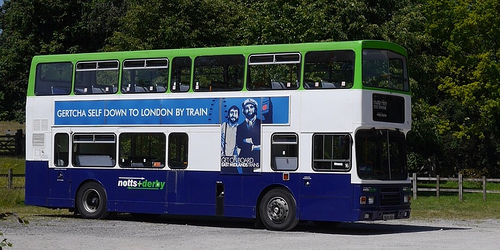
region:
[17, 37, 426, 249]
A double decker bus that is blue white and green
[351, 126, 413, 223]
The windshield on the bus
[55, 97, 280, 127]
An advertisement on the bus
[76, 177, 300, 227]
The wheels on the bus go round and round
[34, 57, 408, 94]
The upper deck of the bus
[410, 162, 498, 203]
A fence made from hedge posts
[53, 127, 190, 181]
Windows for the passengers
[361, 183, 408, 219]
Headlights on the front of the bus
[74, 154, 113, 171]
A seat inside the bus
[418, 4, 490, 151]
The trees are full and green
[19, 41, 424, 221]
blue, white, and green bus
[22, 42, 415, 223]
double decket bus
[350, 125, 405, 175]
front windshield of bus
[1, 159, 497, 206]
wood fenceline behind bus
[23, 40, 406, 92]
green top of bus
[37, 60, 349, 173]
windows on side of bus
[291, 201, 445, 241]
shadow of bus on road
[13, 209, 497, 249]
road bus is on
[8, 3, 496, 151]
trees behind the fenceline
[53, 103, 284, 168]
advertisement printed on side of bus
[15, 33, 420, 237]
a double-decker bus driving down a wooded road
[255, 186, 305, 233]
a front wheel of a double-decker bus driving down the road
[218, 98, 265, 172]
a picture of two men on the side of a double-decker bus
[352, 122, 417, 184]
the front window of a double-decker bus driving down a road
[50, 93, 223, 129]
words on a sign on a double-decker bus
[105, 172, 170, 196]
words on a sign on a double-decker bus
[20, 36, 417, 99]
the top part of a double-decker bus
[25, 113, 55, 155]
vents on the back side of a double-decker bus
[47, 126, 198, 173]
windows on the side of a double-decker bus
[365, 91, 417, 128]
the middle front window on a double-decker bus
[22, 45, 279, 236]
This is a bus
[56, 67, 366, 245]
The bus is green, white and blue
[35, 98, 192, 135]
This is a sign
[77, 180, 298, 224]
These are wheels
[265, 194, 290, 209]
The wheel is silver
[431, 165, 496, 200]
This is a wooden fence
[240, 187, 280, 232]
This is a black tire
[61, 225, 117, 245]
This is a stone pavement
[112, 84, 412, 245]
The bus has two floors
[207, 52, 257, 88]
These are windows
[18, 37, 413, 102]
THE TOP OF THE BUS IS GREEN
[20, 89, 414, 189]
THE MIDDLE OF THE BUS IS WHITE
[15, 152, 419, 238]
THE BOTTOM OF THE BUS IS BLUE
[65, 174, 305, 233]
THE BUS HAS BLACK TIRES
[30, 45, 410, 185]
THE BUS HAS MANY WINDOWS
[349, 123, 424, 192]
THE BUS HAS A LARGE WINDSHIELD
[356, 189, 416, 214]
THE BUS HAS LIGHTS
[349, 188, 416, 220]
THE LIGHTS ON THE BUS ARE NOT ON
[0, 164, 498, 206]
THE FENCE IS WOODEN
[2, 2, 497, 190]
THE TREES BEHIND THE BUS ARE LUSH AND GREEN